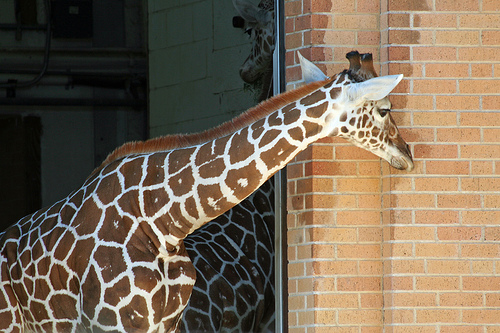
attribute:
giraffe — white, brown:
[37, 32, 427, 326]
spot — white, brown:
[282, 102, 299, 126]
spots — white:
[234, 176, 246, 189]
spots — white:
[202, 190, 219, 210]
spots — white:
[173, 176, 186, 187]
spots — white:
[105, 215, 125, 235]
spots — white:
[126, 308, 149, 322]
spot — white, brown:
[258, 114, 293, 138]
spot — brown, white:
[287, 122, 304, 144]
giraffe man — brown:
[66, 72, 338, 184]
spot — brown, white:
[194, 147, 222, 180]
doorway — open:
[1, 0, 283, 331]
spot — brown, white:
[299, 90, 324, 107]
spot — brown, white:
[257, 137, 298, 167]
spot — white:
[193, 181, 235, 216]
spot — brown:
[195, 134, 228, 161]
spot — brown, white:
[163, 163, 198, 196]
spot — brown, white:
[141, 145, 169, 187]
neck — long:
[151, 96, 311, 238]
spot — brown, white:
[224, 160, 262, 199]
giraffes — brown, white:
[2, 62, 396, 321]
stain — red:
[284, 6, 344, 236]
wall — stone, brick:
[281, 3, 498, 328]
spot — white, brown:
[163, 147, 194, 168]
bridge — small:
[107, 95, 151, 111]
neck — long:
[108, 129, 259, 188]